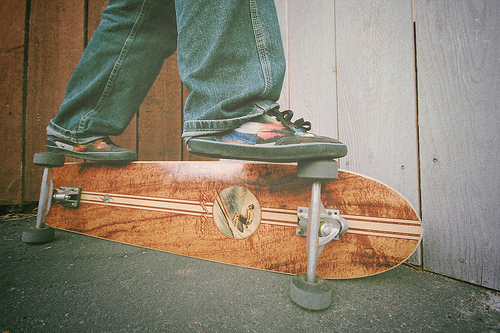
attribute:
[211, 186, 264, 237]
graphic — round, printed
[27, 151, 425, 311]
skateboard — brown, wooden , WOOD, sideways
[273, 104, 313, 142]
shoelace — black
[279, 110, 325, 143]
lace — black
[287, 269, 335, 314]
wheel — black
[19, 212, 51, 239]
wheel — black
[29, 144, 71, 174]
wheel — black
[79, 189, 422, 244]
stripe — tan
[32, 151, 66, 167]
wheel — gray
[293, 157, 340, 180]
wheel — gray, black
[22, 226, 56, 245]
wheel — gray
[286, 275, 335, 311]
wheel — gray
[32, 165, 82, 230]
truck — gray 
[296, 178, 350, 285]
truck — gray 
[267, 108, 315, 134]
shoe lace — black 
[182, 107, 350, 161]
shoe — colorful, black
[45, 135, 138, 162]
shoe — colorful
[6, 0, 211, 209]
wall — wooden, brown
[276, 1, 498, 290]
wall — gray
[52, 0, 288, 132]
jeans — blue